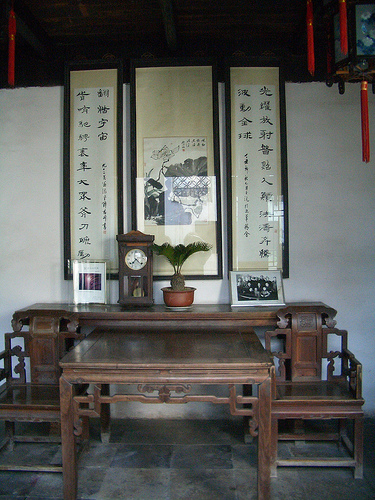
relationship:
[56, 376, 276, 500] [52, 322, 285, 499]
legs under table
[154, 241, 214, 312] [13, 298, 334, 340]
plant on top of table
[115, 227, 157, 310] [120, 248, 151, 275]
clock has face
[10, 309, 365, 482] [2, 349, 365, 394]
chair has arms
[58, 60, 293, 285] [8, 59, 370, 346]
art on wall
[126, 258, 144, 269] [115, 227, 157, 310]
hands on clock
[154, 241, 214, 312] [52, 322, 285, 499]
plant on table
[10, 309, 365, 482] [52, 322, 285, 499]
chair near table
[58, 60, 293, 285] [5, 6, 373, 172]
art under tassels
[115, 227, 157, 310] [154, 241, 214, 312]
clock near plant